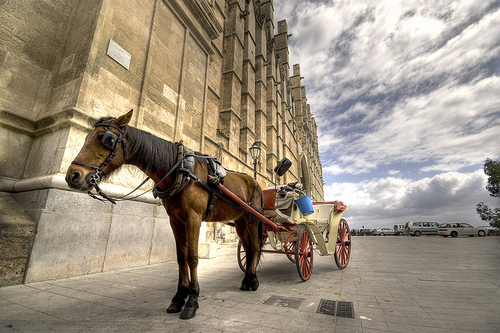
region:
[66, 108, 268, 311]
brown horse in the ground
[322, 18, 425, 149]
cloudy sky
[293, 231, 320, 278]
red wheels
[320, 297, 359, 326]
drainage on the ground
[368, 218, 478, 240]
car parked on the side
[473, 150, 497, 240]
trees on the right side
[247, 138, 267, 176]
street lamp behind the horse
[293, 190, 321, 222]
blue pale hanging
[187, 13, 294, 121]
a huge building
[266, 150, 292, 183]
side mirror of the trolley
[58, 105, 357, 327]
A horse and carriage near a building structure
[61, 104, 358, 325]
A parked horse and carriage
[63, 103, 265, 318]
the horse pulling the cart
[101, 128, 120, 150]
the black block on the face of the horse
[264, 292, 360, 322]
the grates on the gorund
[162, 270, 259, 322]
the balck hooves of the horse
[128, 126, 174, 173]
the hair on the neck of the horse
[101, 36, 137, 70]
the white plaque on the wall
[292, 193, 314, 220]
the blue buket on the wagon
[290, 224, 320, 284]
the red wheel of the wagon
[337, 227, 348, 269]
the spokes on the wheel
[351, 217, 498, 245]
the cars parked in a row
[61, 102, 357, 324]
A horse and carriage parked on a stone road